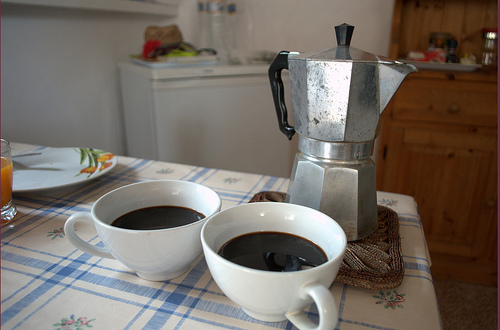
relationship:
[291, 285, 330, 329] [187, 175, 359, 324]
handle on cup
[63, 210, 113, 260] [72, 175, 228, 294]
handle on cup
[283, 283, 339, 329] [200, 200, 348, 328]
handle on cup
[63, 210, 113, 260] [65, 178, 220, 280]
handle on cup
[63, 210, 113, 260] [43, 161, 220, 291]
handle on cup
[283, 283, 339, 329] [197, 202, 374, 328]
handle on cup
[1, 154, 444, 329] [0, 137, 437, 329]
table cloth on table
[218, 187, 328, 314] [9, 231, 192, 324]
cup on table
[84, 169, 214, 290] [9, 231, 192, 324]
cup on table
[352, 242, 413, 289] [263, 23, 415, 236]
hotplate under espresso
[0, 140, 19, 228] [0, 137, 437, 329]
drinking glass on table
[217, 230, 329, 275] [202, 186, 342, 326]
espresso in coffee cup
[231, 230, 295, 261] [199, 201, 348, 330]
espresso in cup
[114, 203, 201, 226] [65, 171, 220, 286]
coffee in cup